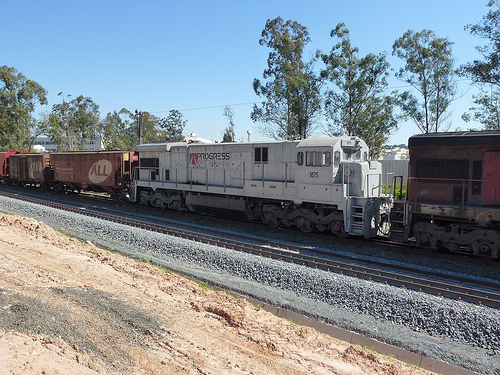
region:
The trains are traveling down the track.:
[0, 112, 496, 244]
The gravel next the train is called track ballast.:
[145, 273, 460, 373]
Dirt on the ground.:
[23, 280, 233, 370]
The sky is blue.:
[110, 8, 220, 48]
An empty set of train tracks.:
[153, 215, 468, 325]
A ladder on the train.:
[337, 180, 367, 231]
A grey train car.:
[126, 116, 396, 238]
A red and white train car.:
[45, 135, 137, 195]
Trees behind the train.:
[242, 10, 497, 130]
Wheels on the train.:
[255, 202, 344, 236]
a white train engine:
[123, 136, 384, 236]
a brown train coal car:
[48, 146, 132, 200]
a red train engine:
[383, 125, 498, 253]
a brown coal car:
[8, 148, 52, 193]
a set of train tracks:
[5, 185, 497, 327]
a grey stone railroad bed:
[2, 186, 499, 353]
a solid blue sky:
[5, 1, 496, 133]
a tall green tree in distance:
[254, 14, 319, 141]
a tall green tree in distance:
[316, 19, 393, 152]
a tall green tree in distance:
[386, 27, 456, 131]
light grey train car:
[124, 130, 393, 242]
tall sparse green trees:
[242, 14, 467, 165]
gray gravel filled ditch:
[1, 191, 498, 370]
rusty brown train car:
[44, 144, 138, 190]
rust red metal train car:
[395, 129, 498, 254]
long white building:
[13, 129, 106, 154]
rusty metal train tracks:
[5, 185, 498, 310]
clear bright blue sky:
[1, 0, 496, 150]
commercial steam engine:
[0, 119, 499, 262]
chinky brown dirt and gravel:
[5, 214, 405, 371]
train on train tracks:
[2, 129, 497, 256]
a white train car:
[128, 136, 391, 238]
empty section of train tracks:
[0, 187, 496, 314]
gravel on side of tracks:
[0, 193, 499, 357]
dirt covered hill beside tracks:
[1, 214, 428, 374]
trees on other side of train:
[1, 0, 498, 150]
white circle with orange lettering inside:
[86, 157, 115, 187]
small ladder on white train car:
[346, 197, 371, 236]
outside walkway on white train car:
[124, 156, 300, 193]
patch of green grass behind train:
[381, 183, 406, 201]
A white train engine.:
[135, 135, 390, 227]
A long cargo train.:
[4, 148, 489, 242]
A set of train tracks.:
[7, 195, 498, 281]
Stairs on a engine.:
[344, 192, 379, 238]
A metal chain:
[375, 219, 397, 236]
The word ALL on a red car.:
[82, 159, 114, 184]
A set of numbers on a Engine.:
[305, 168, 322, 180]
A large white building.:
[25, 134, 120, 153]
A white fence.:
[377, 154, 411, 191]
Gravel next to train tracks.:
[224, 254, 308, 303]